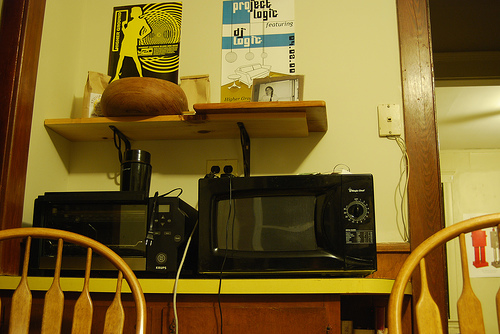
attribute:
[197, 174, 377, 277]
microwave — black, unplugged, electric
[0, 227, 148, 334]
chair — wooden, goldenrod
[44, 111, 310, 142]
shelf — wooden, brown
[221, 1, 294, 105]
sign — colorful, white, blue, blue,black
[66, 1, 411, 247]
wall — beige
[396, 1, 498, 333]
door frame — wooden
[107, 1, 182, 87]
picture — black, yellow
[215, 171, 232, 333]
cord — black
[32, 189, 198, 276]
toaster oven — black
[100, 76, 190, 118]
bowl — rounded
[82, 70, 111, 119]
paper bag — small